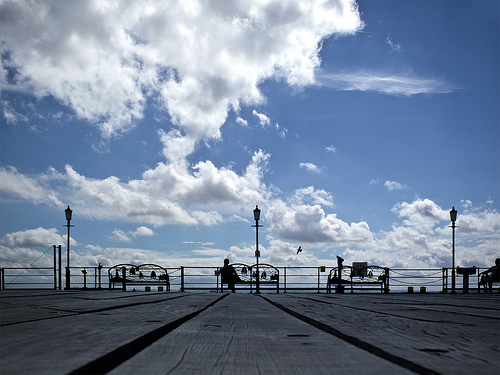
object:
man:
[213, 259, 242, 292]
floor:
[0, 288, 499, 374]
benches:
[327, 265, 391, 294]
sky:
[1, 0, 499, 290]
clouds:
[268, 188, 500, 267]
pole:
[450, 220, 456, 294]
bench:
[107, 263, 169, 293]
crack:
[64, 291, 233, 374]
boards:
[110, 291, 415, 374]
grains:
[148, 339, 243, 366]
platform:
[3, 282, 500, 374]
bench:
[216, 263, 280, 293]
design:
[109, 263, 170, 281]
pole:
[254, 227, 261, 297]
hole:
[293, 342, 316, 346]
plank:
[105, 292, 416, 374]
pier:
[0, 291, 499, 374]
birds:
[296, 246, 305, 254]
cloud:
[0, 0, 363, 133]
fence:
[0, 265, 500, 293]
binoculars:
[335, 255, 344, 265]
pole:
[337, 256, 344, 295]